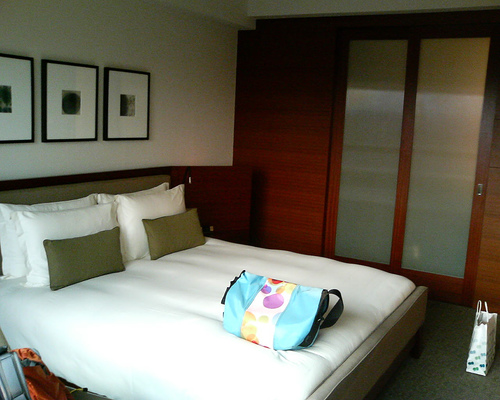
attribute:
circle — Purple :
[263, 293, 282, 308]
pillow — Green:
[146, 215, 213, 251]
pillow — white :
[0, 192, 97, 279]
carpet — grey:
[404, 307, 496, 399]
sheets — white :
[0, 233, 416, 394]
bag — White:
[212, 257, 359, 354]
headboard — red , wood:
[1, 161, 258, 282]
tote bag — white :
[220, 268, 342, 352]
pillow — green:
[143, 208, 205, 261]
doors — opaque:
[320, 20, 498, 311]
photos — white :
[32, 57, 249, 159]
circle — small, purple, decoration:
[261, 291, 284, 311]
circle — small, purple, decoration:
[259, 284, 277, 295]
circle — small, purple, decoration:
[268, 276, 282, 283]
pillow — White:
[17, 195, 135, 285]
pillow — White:
[101, 180, 217, 265]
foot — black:
[402, 329, 427, 366]